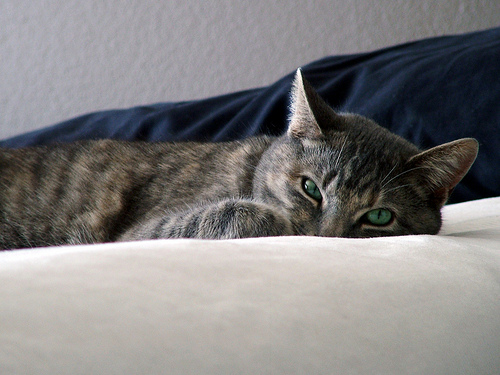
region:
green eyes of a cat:
[253, 172, 421, 242]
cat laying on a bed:
[11, 68, 478, 270]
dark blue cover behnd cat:
[65, 18, 497, 163]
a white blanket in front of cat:
[24, 185, 486, 366]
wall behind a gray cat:
[24, 1, 434, 164]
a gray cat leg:
[136, 193, 276, 263]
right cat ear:
[254, 63, 348, 145]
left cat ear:
[394, 132, 486, 175]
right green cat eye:
[278, 161, 331, 219]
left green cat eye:
[351, 196, 408, 238]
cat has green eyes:
[301, 164, 406, 233]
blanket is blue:
[19, 0, 498, 160]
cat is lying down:
[18, 229, 440, 255]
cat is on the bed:
[0, 215, 443, 283]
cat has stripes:
[13, 148, 138, 234]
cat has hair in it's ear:
[410, 142, 479, 187]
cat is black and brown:
[63, 153, 281, 187]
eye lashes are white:
[364, 161, 418, 205]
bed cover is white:
[15, 224, 433, 342]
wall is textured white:
[9, 4, 452, 73]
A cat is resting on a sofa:
[17, 40, 493, 300]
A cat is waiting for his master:
[16, 33, 488, 330]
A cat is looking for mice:
[55, 51, 496, 342]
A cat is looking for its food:
[57, 50, 497, 340]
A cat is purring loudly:
[0, 36, 488, 336]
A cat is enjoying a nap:
[15, 45, 493, 326]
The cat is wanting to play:
[5, 52, 482, 332]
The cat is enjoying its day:
[15, 45, 490, 363]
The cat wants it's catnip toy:
[5, 45, 496, 346]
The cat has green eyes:
[87, 38, 498, 329]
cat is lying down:
[8, 95, 474, 252]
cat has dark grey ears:
[245, 53, 482, 178]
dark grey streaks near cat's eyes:
[319, 144, 389, 197]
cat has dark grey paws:
[155, 195, 275, 242]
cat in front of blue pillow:
[27, 53, 497, 206]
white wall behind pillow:
[23, 1, 243, 117]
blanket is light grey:
[32, 235, 460, 355]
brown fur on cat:
[18, 152, 263, 220]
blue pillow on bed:
[252, 35, 497, 187]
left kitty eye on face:
[366, 203, 394, 226]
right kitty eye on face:
[303, 174, 323, 209]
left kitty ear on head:
[426, 140, 470, 190]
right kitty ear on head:
[292, 62, 326, 143]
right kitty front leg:
[150, 211, 267, 238]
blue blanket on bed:
[31, 103, 218, 125]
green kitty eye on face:
[372, 203, 394, 224]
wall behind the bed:
[45, 18, 152, 75]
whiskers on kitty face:
[382, 161, 417, 191]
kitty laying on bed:
[3, 66, 473, 241]